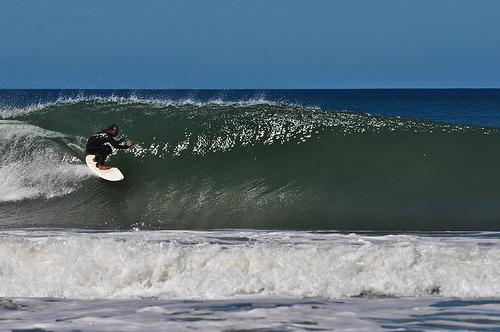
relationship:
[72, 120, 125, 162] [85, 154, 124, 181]
man on board